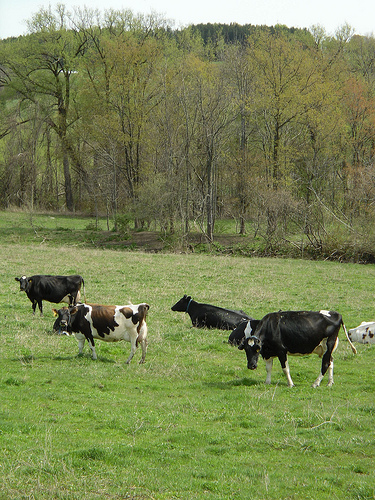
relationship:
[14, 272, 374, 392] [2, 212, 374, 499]
cows in field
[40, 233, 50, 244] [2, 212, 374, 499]
stick on grass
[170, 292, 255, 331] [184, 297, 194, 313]
cow has collar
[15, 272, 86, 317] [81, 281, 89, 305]
cow has tail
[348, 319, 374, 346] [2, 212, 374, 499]
cow in field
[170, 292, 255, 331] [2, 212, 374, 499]
cow on grass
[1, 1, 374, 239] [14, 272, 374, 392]
trees behind cows